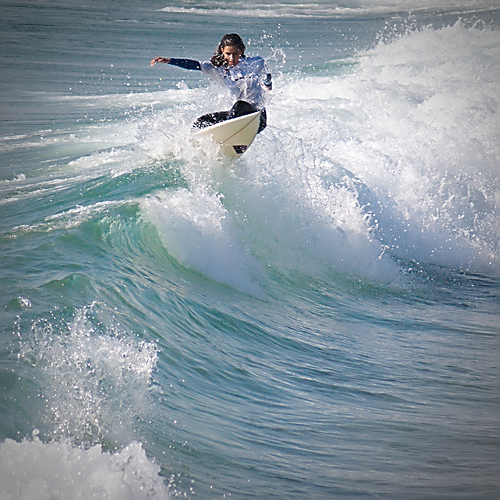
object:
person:
[150, 32, 273, 136]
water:
[0, 1, 500, 500]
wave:
[166, 7, 497, 285]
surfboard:
[187, 111, 261, 172]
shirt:
[198, 55, 268, 110]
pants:
[192, 100, 268, 132]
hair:
[209, 33, 245, 68]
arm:
[170, 57, 217, 72]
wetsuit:
[168, 56, 273, 134]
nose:
[229, 54, 236, 62]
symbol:
[232, 144, 248, 155]